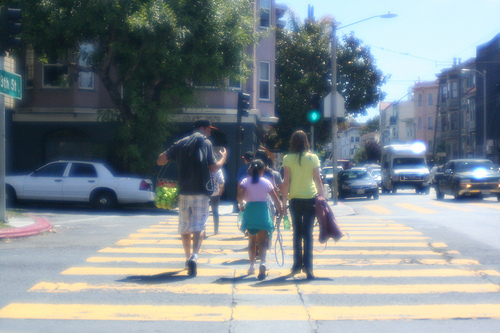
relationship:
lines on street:
[6, 211, 452, 316] [55, 197, 465, 317]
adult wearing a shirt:
[280, 129, 325, 280] [282, 150, 321, 200]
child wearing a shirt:
[236, 158, 282, 277] [235, 177, 273, 202]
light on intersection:
[305, 82, 324, 140] [47, 199, 484, 311]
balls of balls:
[154, 187, 178, 209] [157, 187, 175, 209]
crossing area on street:
[76, 210, 440, 314] [37, 187, 475, 317]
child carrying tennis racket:
[236, 158, 282, 277] [273, 210, 290, 268]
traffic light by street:
[305, 106, 322, 142] [338, 163, 499, 331]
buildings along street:
[333, 32, 498, 162] [351, 155, 499, 330]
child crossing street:
[236, 158, 282, 277] [2, 193, 498, 329]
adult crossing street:
[157, 118, 227, 280] [2, 193, 498, 329]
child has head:
[236, 158, 282, 277] [247, 154, 267, 181]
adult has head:
[280, 129, 325, 280] [291, 128, 312, 155]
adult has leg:
[157, 118, 227, 280] [192, 206, 204, 266]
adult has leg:
[280, 129, 325, 280] [258, 232, 268, 273]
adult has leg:
[280, 129, 325, 280] [300, 208, 314, 280]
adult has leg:
[157, 118, 227, 280] [192, 229, 201, 265]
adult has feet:
[157, 118, 227, 280] [181, 249, 200, 279]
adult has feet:
[280, 129, 325, 280] [248, 260, 272, 280]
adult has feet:
[280, 129, 325, 280] [284, 259, 316, 280]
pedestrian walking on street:
[0, 190, 499, 330] [281, 128, 324, 286]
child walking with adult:
[235, 155, 283, 276] [278, 123, 327, 286]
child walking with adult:
[235, 155, 283, 276] [159, 118, 229, 290]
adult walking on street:
[157, 118, 227, 280] [2, 193, 498, 329]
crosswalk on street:
[0, 206, 498, 330] [2, 178, 488, 330]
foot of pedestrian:
[181, 253, 203, 280] [147, 102, 236, 282]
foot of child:
[250, 257, 274, 286] [225, 140, 289, 293]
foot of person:
[300, 261, 326, 286] [269, 119, 352, 285]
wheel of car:
[83, 183, 125, 223] [2, 143, 168, 216]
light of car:
[131, 173, 160, 194] [2, 151, 166, 217]